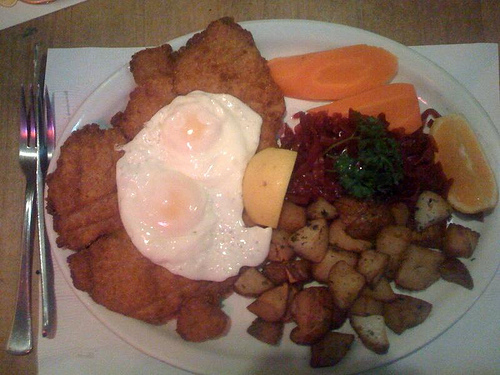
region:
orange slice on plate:
[424, 110, 498, 215]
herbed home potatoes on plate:
[225, 197, 486, 373]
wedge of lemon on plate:
[244, 135, 300, 231]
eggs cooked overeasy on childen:
[111, 86, 271, 282]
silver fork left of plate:
[7, 77, 41, 354]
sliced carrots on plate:
[265, 37, 427, 134]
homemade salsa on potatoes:
[283, 105, 454, 210]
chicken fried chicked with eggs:
[39, 12, 289, 347]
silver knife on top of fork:
[28, 40, 53, 345]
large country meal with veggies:
[38, 12, 498, 369]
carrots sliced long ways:
[270, 38, 430, 135]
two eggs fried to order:
[122, 81, 260, 286]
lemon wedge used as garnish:
[240, 136, 300, 235]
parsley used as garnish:
[329, 112, 404, 227]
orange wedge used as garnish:
[427, 108, 498, 230]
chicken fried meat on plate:
[47, 17, 297, 373]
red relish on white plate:
[289, 105, 448, 210]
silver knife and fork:
[13, 29, 58, 374]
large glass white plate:
[55, 2, 494, 373]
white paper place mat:
[22, 20, 497, 366]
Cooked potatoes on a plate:
[271, 213, 423, 355]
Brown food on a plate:
[56, 160, 241, 367]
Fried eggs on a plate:
[126, 94, 293, 371]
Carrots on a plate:
[267, 24, 422, 151]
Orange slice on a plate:
[425, 98, 498, 200]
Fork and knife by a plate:
[12, 54, 87, 374]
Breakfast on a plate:
[68, 38, 478, 369]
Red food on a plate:
[276, 113, 386, 223]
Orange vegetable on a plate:
[263, 31, 442, 160]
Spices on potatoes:
[272, 200, 409, 342]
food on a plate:
[44, 35, 489, 352]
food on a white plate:
[78, 45, 492, 348]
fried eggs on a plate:
[106, 75, 309, 312]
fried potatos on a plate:
[230, 198, 459, 358]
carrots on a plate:
[241, 30, 418, 141]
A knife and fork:
[3, 78, 77, 361]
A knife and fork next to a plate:
[15, 73, 140, 359]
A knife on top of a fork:
[5, 77, 90, 374]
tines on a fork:
[15, 83, 66, 161]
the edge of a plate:
[34, 223, 167, 372]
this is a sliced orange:
[454, 119, 473, 194]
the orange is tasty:
[458, 123, 479, 205]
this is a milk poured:
[139, 106, 231, 248]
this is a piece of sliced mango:
[291, 50, 387, 92]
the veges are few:
[346, 130, 395, 192]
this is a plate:
[203, 343, 240, 370]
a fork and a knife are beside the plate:
[11, 82, 52, 349]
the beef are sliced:
[281, 220, 442, 331]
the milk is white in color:
[136, 111, 241, 240]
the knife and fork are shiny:
[1, 105, 56, 347]